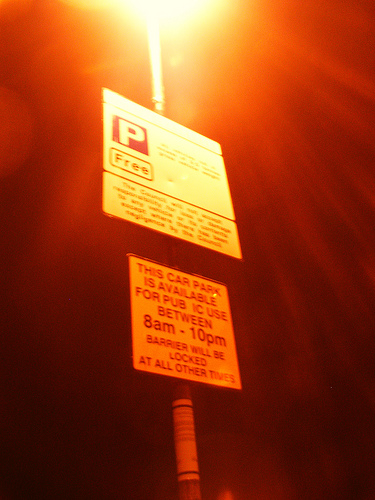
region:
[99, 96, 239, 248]
white parking sign on pole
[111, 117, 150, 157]
red and white sign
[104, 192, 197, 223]
red writing on sign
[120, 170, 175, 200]
red line on bottom of sign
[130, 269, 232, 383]
large square sign on post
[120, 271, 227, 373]
red writing on square sign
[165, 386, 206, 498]
pole with white sign on it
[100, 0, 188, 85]
light on top of pole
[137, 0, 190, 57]
orange light on street pole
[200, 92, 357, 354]
glare of light on sign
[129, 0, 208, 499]
A long metal pole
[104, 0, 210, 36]
an overhanging light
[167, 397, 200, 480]
A sign wrapped on a metal pole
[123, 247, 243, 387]
A black and white sign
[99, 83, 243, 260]
A black and white sign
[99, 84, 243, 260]
a free parking sign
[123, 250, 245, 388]
a sign showing the times a parking lot is open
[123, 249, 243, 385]
a parking time availability sign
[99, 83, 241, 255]
A car park sign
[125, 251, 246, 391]
A sign on a pole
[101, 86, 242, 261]
white sign above a white sign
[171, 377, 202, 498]
metal pole behind a square sign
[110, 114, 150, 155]
red square printed on sign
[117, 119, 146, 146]
white "p" inside a red square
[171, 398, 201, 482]
white paper wrapped around pole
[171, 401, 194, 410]
thin black stripe around pole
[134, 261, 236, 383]
red text printed on a white sign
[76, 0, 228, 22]
bright light at top of the pole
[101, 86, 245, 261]
large sign hanging from a pole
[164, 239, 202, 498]
pole behind sign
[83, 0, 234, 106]
a light on a pole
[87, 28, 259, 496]
two signs on a pole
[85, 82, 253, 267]
a white sign on a pole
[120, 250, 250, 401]
a white sign on a pole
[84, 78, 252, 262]
sign has red letters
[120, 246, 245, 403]
sign has red letters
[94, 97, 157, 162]
the letter P on a sign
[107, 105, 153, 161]
letter P is color white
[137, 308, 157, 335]
number 8 on a sign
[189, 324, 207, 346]
number 10 on a sign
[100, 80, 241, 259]
this is a sign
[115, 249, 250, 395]
this is a sign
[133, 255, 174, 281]
this is a word on a sign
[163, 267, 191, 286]
this is a word on a sign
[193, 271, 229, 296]
this is a word on a sign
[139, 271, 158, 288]
this is a word on a sign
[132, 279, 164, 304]
this is a word on a sign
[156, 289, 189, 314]
this is a word on a sign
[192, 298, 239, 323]
this is a word on a sign